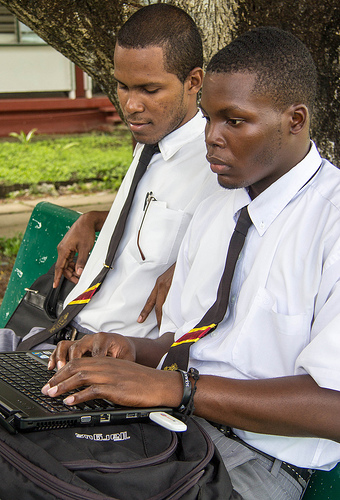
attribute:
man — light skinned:
[52, 10, 215, 340]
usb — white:
[143, 392, 194, 460]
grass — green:
[1, 136, 118, 194]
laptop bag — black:
[2, 418, 234, 498]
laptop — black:
[1, 347, 186, 432]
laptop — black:
[0, 330, 191, 446]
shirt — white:
[128, 159, 338, 443]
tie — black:
[214, 193, 253, 316]